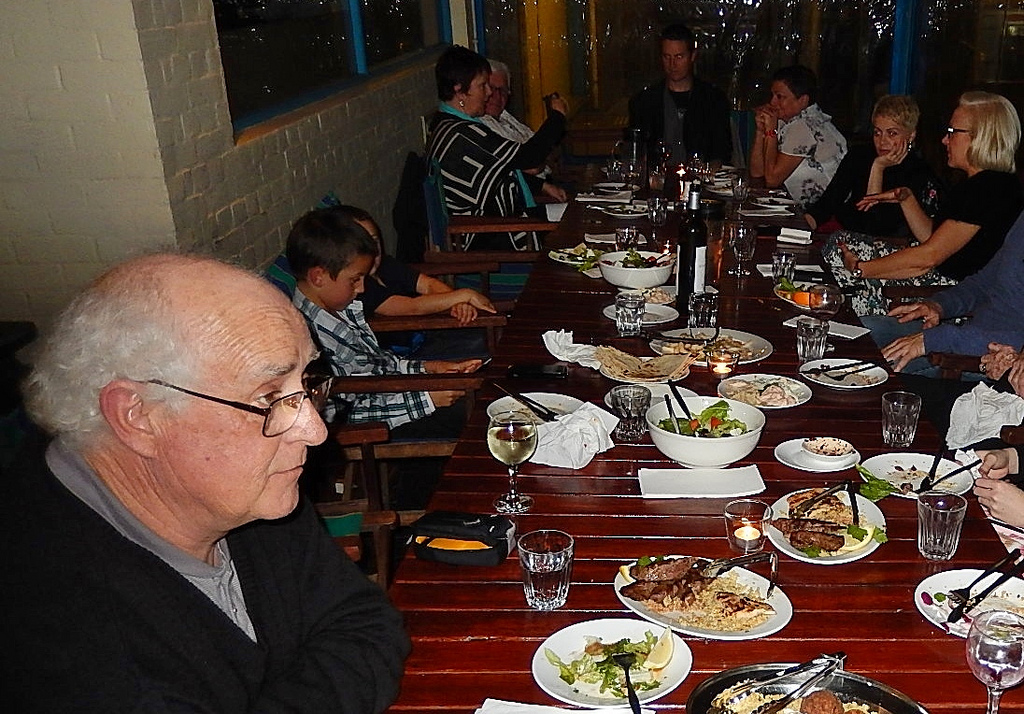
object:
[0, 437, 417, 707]
jacket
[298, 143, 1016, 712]
table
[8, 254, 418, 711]
man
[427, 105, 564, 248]
shirt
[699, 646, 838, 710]
tongs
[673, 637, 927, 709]
platter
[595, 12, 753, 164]
man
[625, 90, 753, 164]
coat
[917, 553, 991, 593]
fork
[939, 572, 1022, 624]
knife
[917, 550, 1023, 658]
plate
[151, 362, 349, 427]
glasses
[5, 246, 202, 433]
hair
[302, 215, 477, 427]
boy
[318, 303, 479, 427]
shirt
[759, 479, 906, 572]
plate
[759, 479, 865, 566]
food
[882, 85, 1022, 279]
lady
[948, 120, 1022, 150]
glasses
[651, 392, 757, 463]
bowl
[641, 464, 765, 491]
napkin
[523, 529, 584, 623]
glass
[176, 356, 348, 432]
eyeglasses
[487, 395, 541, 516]
goblet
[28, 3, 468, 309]
wall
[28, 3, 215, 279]
blocks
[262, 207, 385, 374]
boy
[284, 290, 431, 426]
jacket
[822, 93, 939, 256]
woman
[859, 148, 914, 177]
chin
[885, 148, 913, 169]
hand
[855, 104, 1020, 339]
woman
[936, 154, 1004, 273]
shirt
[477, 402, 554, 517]
glass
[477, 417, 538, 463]
wine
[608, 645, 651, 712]
silverware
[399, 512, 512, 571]
camera case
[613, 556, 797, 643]
plate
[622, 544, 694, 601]
steak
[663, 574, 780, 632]
pasta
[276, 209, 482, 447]
child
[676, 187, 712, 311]
bottle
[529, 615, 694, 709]
plate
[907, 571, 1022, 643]
plate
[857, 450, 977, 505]
plate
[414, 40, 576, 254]
woman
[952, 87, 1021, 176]
hair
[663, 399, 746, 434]
salad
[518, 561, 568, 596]
water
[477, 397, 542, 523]
wine glass